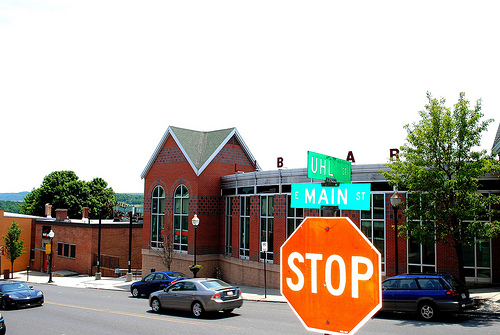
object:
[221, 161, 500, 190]
roof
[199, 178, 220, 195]
red brick.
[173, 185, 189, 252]
window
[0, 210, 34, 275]
building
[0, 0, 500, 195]
sky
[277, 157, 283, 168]
b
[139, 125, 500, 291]
building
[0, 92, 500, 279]
ground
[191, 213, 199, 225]
light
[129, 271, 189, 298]
car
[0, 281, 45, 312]
corvette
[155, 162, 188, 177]
brick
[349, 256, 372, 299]
letter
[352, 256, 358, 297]
white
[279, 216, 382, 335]
sign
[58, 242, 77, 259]
three windows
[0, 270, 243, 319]
three cars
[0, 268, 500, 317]
sidewalk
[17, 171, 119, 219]
leaves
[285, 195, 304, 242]
window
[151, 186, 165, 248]
window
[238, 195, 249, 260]
window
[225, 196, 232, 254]
window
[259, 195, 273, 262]
window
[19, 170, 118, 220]
trees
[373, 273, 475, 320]
car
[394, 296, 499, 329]
shade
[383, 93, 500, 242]
leaves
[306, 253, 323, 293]
white letter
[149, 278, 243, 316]
car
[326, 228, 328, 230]
bolt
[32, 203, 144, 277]
building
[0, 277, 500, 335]
street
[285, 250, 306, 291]
letters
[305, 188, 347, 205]
main street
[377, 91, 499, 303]
tree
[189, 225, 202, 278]
pole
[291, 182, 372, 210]
street sign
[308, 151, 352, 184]
street sign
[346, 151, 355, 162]
letter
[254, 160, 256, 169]
letter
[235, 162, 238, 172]
letter